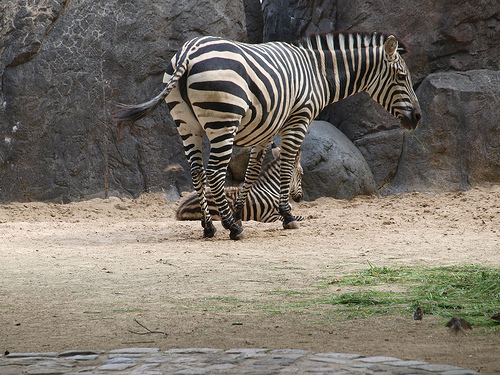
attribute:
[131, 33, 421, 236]
zebra — adult, walking, standing, small, black, white, looking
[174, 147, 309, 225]
zebra — baby, looking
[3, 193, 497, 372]
ground — soft, dirt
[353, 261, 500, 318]
grass — green, small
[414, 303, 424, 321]
bird — tiny, black, small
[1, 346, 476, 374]
stones — gray, flat, path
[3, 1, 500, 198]
wall — rock, large, gray, white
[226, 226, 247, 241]
hoof — black, sturdy, white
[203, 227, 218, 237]
hoof — black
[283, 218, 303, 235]
hoof — black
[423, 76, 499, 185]
boulder — small, grey, large, big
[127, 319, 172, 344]
stick — small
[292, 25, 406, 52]
mane — black, white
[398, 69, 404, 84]
eye — black